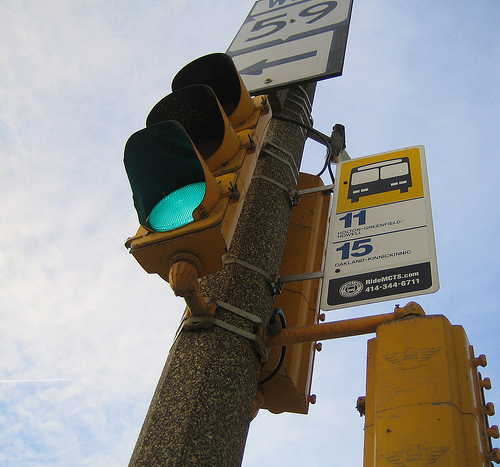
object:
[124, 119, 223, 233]
covers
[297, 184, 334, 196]
bar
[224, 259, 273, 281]
bracket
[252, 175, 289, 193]
straps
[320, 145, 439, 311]
sign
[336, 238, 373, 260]
15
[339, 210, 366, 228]
11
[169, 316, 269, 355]
bands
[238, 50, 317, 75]
arrow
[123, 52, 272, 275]
traffic light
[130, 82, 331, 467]
pole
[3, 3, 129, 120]
sky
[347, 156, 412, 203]
bus icon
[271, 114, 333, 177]
cord